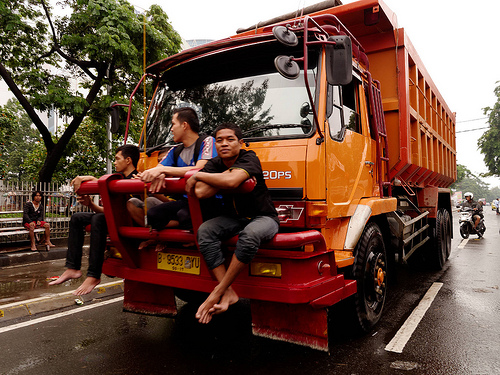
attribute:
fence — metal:
[2, 177, 78, 251]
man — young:
[50, 142, 157, 301]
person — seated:
[18, 186, 60, 252]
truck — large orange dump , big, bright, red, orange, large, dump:
[68, 1, 458, 357]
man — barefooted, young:
[184, 123, 287, 328]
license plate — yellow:
[153, 247, 204, 279]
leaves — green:
[72, 5, 129, 56]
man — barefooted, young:
[128, 102, 224, 247]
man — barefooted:
[37, 140, 147, 300]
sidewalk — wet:
[2, 248, 132, 327]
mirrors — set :
[274, 19, 379, 135]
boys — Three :
[66, 112, 288, 322]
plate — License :
[152, 254, 209, 276]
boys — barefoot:
[66, 108, 277, 311]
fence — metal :
[5, 165, 87, 232]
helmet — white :
[459, 188, 477, 204]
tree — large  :
[2, 0, 182, 180]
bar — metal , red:
[90, 235, 359, 346]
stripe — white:
[385, 270, 450, 360]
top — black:
[189, 150, 279, 225]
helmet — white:
[459, 188, 477, 200]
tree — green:
[30, 62, 80, 118]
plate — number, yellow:
[151, 250, 215, 277]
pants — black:
[65, 206, 105, 284]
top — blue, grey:
[156, 135, 226, 182]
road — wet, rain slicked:
[0, 216, 496, 372]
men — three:
[48, 103, 288, 335]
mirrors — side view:
[263, 10, 361, 98]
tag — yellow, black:
[147, 249, 219, 280]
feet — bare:
[194, 281, 237, 325]